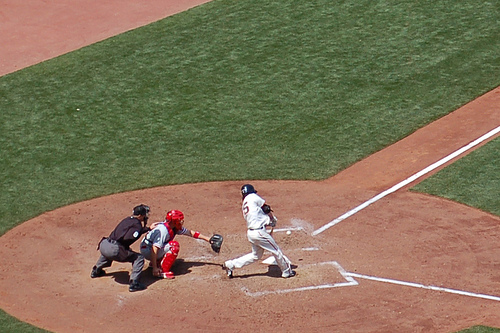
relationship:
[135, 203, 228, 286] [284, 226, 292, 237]
player catch ball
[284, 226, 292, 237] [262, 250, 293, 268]
ball over plate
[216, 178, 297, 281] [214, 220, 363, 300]
batter in box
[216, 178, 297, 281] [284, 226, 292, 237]
batter hitting ball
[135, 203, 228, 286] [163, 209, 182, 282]
player wearing gear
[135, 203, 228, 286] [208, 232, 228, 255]
player has mitt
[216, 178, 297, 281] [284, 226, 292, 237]
batter hit ball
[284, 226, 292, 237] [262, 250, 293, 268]
ball above plate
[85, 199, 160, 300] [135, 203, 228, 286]
umpire behind player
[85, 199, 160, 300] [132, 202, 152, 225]
umpire has mask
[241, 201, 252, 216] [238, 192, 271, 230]
five on shirt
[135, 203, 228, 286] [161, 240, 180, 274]
player has guards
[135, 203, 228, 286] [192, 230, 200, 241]
player has band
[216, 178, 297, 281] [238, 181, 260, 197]
batter wearing helmet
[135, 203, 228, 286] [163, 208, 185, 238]
player wearing helmet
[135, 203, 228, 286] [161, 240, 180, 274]
player wearing guards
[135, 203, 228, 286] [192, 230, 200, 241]
player wearing band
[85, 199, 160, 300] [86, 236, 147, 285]
umpire wearing pants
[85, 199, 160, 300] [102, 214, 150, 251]
umpire wearing shirt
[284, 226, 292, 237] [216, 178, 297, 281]
ball front batter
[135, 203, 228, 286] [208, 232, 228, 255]
player wearing mitt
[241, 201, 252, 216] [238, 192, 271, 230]
5 on shirt